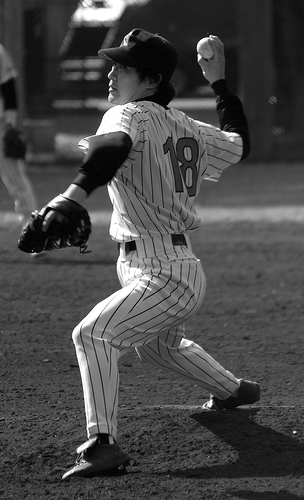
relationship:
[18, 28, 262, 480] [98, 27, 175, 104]
baseball player has head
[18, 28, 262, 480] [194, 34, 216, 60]
baseball player throwing ball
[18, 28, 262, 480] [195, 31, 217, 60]
baseball player throw ball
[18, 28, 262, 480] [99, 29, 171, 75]
baseball player have cap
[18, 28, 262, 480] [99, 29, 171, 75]
baseball player has cap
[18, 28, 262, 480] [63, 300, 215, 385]
baseball player bending bent knees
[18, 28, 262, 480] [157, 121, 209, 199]
baseball player has number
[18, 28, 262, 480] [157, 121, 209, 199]
baseball player have number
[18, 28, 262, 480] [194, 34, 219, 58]
baseball player holding baseball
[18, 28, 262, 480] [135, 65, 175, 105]
baseball player have hair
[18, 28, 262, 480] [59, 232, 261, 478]
baseball player wearing pants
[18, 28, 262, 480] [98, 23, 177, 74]
baseball player wearing hat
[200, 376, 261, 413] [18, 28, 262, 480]
foot on baseball player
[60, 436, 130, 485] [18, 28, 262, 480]
foot on baseball player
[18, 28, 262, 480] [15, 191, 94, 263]
baseball player wearing a baseball glove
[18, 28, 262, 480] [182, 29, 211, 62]
baseball player throwing a baseball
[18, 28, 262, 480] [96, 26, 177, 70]
baseball player wearing a hat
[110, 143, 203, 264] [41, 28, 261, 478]
striped shirt on a man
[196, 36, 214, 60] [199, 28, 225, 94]
ball in hand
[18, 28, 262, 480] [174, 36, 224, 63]
baseball player ready to throw a ball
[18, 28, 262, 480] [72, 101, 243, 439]
baseball player wearing a striped uniform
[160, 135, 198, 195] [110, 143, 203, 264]
number 18 on striped shirt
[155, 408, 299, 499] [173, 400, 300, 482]
shadows on dirt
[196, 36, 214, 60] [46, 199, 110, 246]
ball in hand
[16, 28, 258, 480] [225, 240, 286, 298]
baseball player on field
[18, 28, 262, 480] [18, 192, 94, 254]
baseball player holding baseball glove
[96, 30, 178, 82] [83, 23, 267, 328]
head on man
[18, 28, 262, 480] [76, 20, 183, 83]
baseball player wearing cap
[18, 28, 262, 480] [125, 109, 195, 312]
baseball player wearing uniform